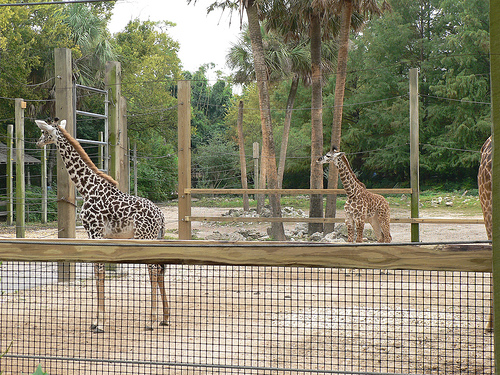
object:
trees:
[0, 0, 500, 241]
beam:
[184, 189, 413, 194]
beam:
[185, 216, 484, 225]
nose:
[35, 141, 39, 146]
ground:
[0, 191, 494, 375]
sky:
[98, 0, 250, 93]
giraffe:
[34, 116, 168, 333]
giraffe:
[477, 135, 495, 332]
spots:
[80, 194, 162, 240]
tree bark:
[243, 0, 288, 240]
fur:
[51, 124, 165, 276]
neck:
[56, 125, 119, 188]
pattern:
[100, 200, 132, 216]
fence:
[1, 258, 500, 372]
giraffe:
[316, 145, 393, 243]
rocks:
[221, 204, 368, 242]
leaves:
[0, 0, 489, 220]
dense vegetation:
[0, 0, 489, 223]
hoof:
[159, 320, 169, 326]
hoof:
[144, 325, 153, 331]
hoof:
[93, 326, 105, 333]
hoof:
[91, 323, 96, 329]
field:
[0, 134, 490, 375]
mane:
[335, 151, 367, 190]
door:
[76, 84, 110, 231]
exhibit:
[0, 0, 500, 375]